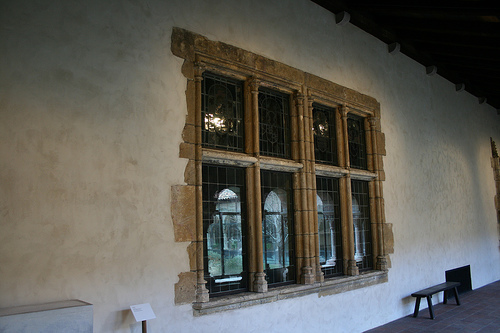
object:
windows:
[192, 62, 252, 157]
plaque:
[129, 302, 158, 323]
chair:
[408, 281, 464, 320]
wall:
[0, 0, 500, 333]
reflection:
[259, 169, 297, 285]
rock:
[170, 269, 197, 308]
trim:
[191, 50, 390, 311]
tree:
[260, 190, 290, 270]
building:
[0, 0, 500, 333]